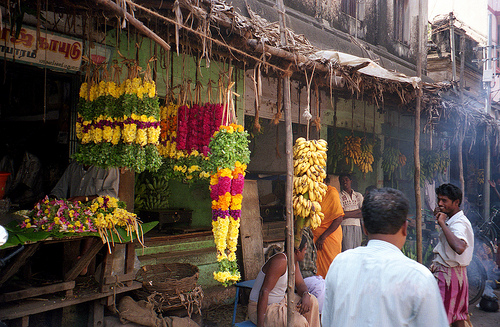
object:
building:
[3, 0, 500, 319]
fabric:
[429, 263, 472, 325]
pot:
[479, 291, 498, 313]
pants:
[248, 293, 324, 327]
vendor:
[305, 181, 345, 278]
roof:
[1, 0, 427, 99]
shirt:
[431, 210, 473, 268]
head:
[362, 185, 410, 250]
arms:
[444, 222, 469, 256]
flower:
[82, 226, 86, 231]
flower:
[54, 216, 60, 225]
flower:
[74, 200, 81, 209]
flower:
[36, 202, 42, 210]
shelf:
[3, 231, 115, 304]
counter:
[3, 273, 143, 323]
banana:
[318, 193, 322, 202]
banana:
[318, 158, 324, 165]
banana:
[294, 159, 299, 167]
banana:
[297, 207, 302, 216]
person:
[336, 171, 365, 251]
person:
[300, 186, 448, 326]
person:
[249, 232, 323, 325]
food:
[29, 197, 128, 236]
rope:
[227, 67, 238, 127]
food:
[202, 121, 251, 287]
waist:
[428, 255, 471, 278]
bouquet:
[24, 194, 133, 237]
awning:
[314, 48, 422, 99]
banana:
[296, 137, 306, 142]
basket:
[133, 263, 203, 317]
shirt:
[315, 239, 448, 327]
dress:
[315, 181, 344, 275]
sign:
[0, 24, 83, 74]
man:
[420, 180, 472, 325]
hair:
[360, 185, 411, 236]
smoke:
[473, 242, 500, 298]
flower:
[147, 84, 157, 98]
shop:
[4, 13, 344, 325]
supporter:
[253, 44, 417, 102]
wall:
[116, 36, 224, 108]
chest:
[280, 264, 289, 287]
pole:
[284, 74, 295, 326]